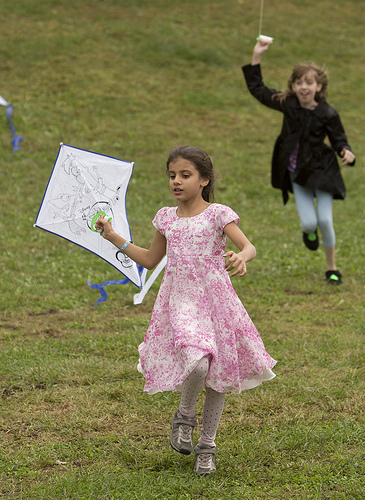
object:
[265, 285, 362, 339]
grass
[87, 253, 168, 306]
streamer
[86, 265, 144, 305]
blue tail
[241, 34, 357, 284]
child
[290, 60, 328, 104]
head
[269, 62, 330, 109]
hair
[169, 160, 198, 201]
face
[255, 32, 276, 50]
string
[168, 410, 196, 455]
shoe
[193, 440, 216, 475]
shoe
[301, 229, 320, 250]
shoe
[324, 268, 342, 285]
shoe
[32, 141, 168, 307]
girl kite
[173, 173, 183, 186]
nose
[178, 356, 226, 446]
socks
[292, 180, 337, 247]
jeans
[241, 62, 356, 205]
coat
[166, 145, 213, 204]
hair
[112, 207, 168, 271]
arm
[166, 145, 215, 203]
head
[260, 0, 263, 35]
kite string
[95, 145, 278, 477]
child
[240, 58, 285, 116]
arm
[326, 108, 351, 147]
arm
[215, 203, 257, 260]
arm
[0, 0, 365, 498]
field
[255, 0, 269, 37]
kite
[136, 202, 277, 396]
dress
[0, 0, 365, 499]
yard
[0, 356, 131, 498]
grass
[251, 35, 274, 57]
hand